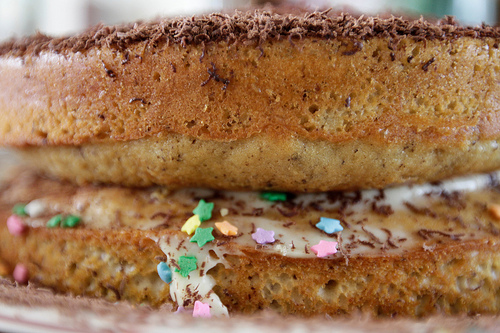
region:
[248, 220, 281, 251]
star shaped sprinkle on bread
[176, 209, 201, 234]
star shaped sprinkle on bread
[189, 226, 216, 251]
star shaped sprinkle on bread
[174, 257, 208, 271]
star shaped sprinkle on bread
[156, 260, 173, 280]
star shaped sprinkle on bread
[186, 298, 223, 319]
star shaped sprinkle on bread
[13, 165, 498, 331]
brown bread of pastry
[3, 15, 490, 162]
brown bread of pastry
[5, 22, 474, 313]
bread pastry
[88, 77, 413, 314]
sprinkles on bread pastry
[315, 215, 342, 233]
the blue star shaped sprinkle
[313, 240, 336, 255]
the pink star shaped sprinkle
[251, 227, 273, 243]
the purple star shaped sprinkle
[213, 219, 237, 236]
the orange star shaped sprinkle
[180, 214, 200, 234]
the yellow star shaped sprinkle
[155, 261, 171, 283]
the blue star shaped sprinkle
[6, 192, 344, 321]
the scattered star shaped sprinkles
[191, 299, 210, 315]
the pink star shaped sprinkle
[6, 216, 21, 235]
the pink star shaped sprinkle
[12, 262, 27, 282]
the pink star shaped sprinkle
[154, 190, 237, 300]
colorful start shaped sprinkles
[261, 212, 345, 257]
colorful start shaped sprinkles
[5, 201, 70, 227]
colorful start shaped sprinkles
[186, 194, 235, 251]
colorful start shaped sprinkles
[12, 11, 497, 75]
chocolate shavings on pancake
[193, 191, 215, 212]
SMALL GREEN STAR SPRINKLE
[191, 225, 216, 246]
SMALL GREEN STAR SPRINKLE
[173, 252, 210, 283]
SMALL GREEN STAR SPRINKLE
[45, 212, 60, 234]
SMALL GREEN STAR SPRINKLE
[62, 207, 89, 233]
SMALL GREEN STAR SPRINKLE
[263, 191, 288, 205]
SMALL GREEN STAR SPRINKLE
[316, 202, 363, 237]
SMALL BLUE STAR SPRINKLE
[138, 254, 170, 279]
SMALL BLUE STAR SPRINKLE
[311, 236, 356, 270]
SMALL PINK STAR SPRINKLE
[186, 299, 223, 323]
SMALL PINK STAR SPRINKLE